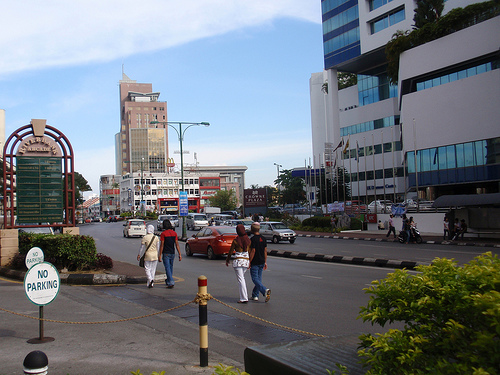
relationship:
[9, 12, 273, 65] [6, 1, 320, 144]
cloud in sky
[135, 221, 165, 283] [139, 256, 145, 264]
woman carrying purse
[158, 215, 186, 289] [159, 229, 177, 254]
person in jacket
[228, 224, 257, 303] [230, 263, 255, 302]
woman has pants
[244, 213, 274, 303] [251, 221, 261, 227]
man has cap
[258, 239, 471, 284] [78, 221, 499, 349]
divider of street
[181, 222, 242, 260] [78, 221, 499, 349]
car in street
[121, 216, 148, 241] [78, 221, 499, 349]
vehicle on street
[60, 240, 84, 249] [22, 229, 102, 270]
leaves of bush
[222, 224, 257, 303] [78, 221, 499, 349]
woman on street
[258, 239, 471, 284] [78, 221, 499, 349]
divider in street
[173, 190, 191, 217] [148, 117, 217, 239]
street sign on street lights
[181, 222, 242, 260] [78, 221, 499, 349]
car on street